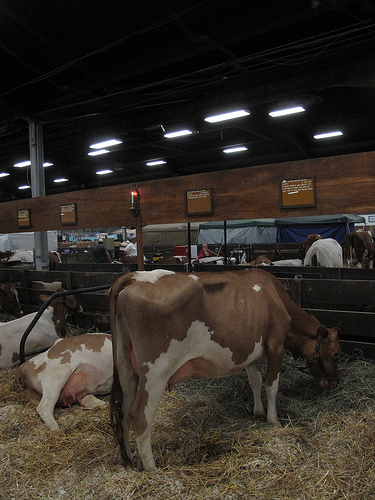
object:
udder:
[55, 381, 88, 411]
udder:
[161, 358, 193, 396]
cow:
[299, 230, 345, 272]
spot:
[188, 275, 199, 282]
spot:
[252, 283, 262, 294]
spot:
[141, 354, 157, 382]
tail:
[106, 267, 132, 471]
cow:
[106, 267, 341, 479]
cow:
[15, 327, 117, 432]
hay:
[1, 323, 372, 499]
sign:
[278, 174, 318, 212]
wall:
[0, 144, 375, 232]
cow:
[0, 289, 89, 370]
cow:
[0, 282, 24, 317]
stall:
[0, 0, 375, 500]